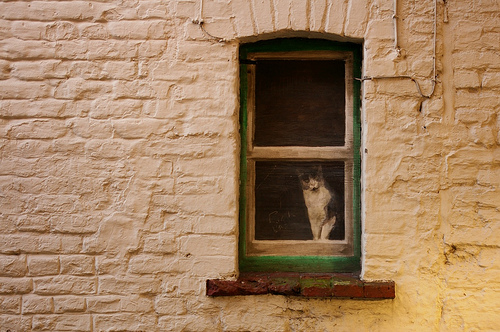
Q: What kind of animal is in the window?
A: Cat.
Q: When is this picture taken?
A: Day time.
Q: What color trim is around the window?
A: Green.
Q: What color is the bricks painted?
A: Beige.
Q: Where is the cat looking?
A: Out of the window.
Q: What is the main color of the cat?
A: White.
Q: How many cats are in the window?
A: One.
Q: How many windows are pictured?
A: One.